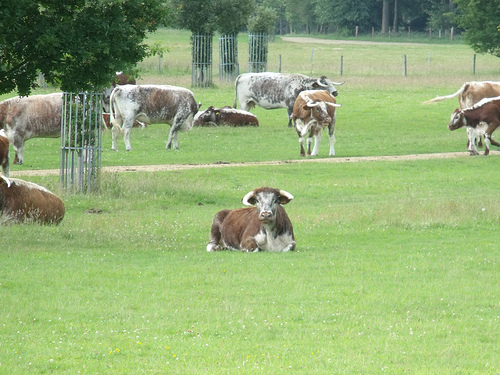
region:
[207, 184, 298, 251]
a brown and white cow resting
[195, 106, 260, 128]
a brown and white cow resting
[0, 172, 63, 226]
a brown and white cow resting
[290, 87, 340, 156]
a brown and white cow standing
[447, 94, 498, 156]
a brown and white cow standing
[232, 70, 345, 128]
a black and white cow standing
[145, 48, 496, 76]
a long chain fence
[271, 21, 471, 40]
a long chain fence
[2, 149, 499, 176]
a long brown path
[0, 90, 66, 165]
a brown and white cow standing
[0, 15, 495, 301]
Nine cows in a grass field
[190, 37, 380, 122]
Spotted brown and white cows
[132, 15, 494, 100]
Fence to a cow pasture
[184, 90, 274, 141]
Cow laying in the grass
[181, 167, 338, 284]
Cute cows with hoofs tucked under him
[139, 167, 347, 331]
Cute brown and white cow looking straight ahead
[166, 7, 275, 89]
Three trees with fences around them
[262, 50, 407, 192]
Two cows looking to the right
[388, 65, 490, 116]
Brown and white cow tail in the air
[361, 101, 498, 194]
Young brown and white cow walking on grass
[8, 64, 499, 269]
cows in the pasture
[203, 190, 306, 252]
cow resting on the ground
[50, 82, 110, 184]
metal enclosure with tree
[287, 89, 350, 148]
cow standing up on ground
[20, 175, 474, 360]
field for cows to walk in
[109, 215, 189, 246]
wild flowers on the ground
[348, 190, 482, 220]
wild grass patches in field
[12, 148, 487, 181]
strip of bare land in field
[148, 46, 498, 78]
fence behind the cows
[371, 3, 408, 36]
trunks of trees in back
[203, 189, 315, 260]
animal sitting on the ground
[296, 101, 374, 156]
animal looking to the left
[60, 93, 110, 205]
fence around the tree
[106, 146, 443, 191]
walkway for the animals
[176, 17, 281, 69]
three trees with fences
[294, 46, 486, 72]
fence surrounding the area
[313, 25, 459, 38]
posts across the road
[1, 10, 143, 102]
branches falling over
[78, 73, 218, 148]
animal looking down on ground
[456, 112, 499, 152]
animal walking different direction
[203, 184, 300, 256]
Brown cow looking at the camera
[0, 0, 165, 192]
Green tree near the cow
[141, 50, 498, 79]
Grey fence near the cow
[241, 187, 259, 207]
white left horn of the cow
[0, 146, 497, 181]
Pathway near the tree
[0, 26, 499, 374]
Green grass field of a farm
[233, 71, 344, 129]
White cow on the grass at the back of the field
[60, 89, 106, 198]
Grey tree guard on the tree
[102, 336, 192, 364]
Small yellow flower on the grass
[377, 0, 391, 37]
Brown tree trunk in the background